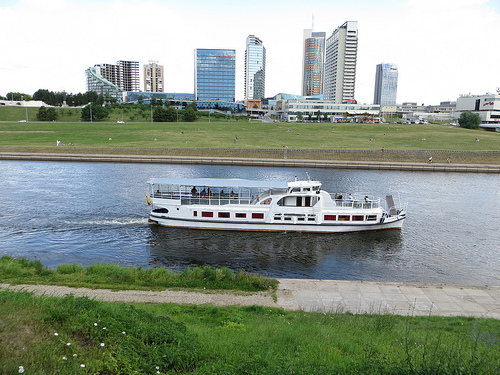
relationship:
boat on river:
[142, 178, 407, 235] [0, 158, 498, 284]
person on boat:
[191, 185, 199, 199] [142, 178, 407, 235]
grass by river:
[0, 247, 274, 294] [0, 158, 498, 284]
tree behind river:
[150, 105, 176, 124] [0, 158, 498, 284]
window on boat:
[322, 213, 336, 220] [142, 178, 407, 235]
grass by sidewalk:
[0, 247, 274, 294] [0, 275, 494, 319]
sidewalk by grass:
[0, 275, 494, 319] [0, 247, 274, 294]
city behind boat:
[18, 19, 470, 125] [142, 178, 407, 235]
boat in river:
[142, 178, 407, 235] [0, 158, 498, 284]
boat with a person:
[142, 178, 407, 235] [191, 185, 199, 199]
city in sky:
[18, 19, 470, 125] [1, 0, 499, 101]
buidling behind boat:
[242, 35, 265, 105] [142, 178, 407, 235]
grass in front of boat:
[0, 247, 274, 294] [142, 178, 407, 235]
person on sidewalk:
[191, 185, 199, 199] [0, 275, 494, 319]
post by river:
[87, 101, 94, 123] [0, 158, 498, 284]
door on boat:
[295, 194, 302, 206] [142, 178, 407, 235]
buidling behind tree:
[242, 35, 265, 105] [150, 105, 176, 124]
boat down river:
[142, 178, 407, 235] [0, 158, 498, 284]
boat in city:
[142, 178, 407, 235] [18, 19, 470, 125]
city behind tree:
[18, 19, 470, 125] [150, 105, 176, 124]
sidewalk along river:
[0, 275, 494, 319] [0, 158, 498, 284]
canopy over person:
[149, 178, 291, 189] [191, 185, 199, 199]